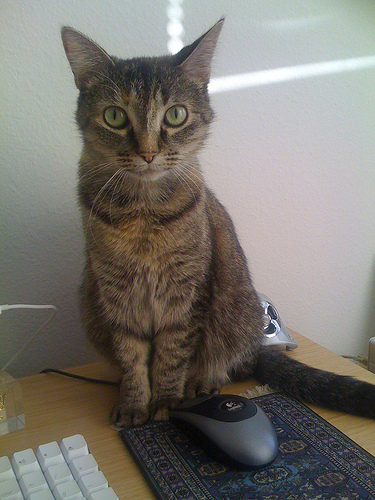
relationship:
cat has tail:
[61, 14, 375, 429] [256, 345, 374, 420]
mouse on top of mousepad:
[168, 393, 280, 472] [109, 382, 375, 499]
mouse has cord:
[168, 393, 280, 472] [38, 368, 120, 388]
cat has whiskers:
[61, 14, 375, 429] [77, 156, 209, 246]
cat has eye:
[61, 14, 375, 429] [166, 103, 188, 126]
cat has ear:
[61, 14, 375, 429] [174, 16, 226, 86]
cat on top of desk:
[61, 14, 375, 429] [0, 325, 375, 500]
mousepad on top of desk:
[109, 382, 375, 499] [0, 325, 375, 500]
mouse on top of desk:
[168, 393, 280, 472] [0, 325, 375, 500]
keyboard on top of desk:
[0, 434, 121, 500] [0, 325, 375, 500]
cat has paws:
[61, 14, 375, 429] [110, 397, 185, 430]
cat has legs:
[61, 14, 375, 429] [85, 256, 208, 396]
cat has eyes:
[61, 14, 375, 429] [102, 104, 188, 126]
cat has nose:
[61, 14, 375, 429] [136, 147, 161, 163]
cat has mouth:
[61, 14, 375, 429] [127, 164, 172, 176]